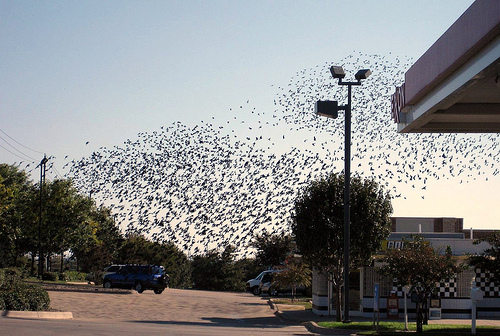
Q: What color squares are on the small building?
A: White and black.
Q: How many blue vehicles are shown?
A: 1.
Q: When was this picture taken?
A: Daytime.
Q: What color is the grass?
A: Green.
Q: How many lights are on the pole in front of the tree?
A: 3.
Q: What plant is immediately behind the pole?
A: Tree.